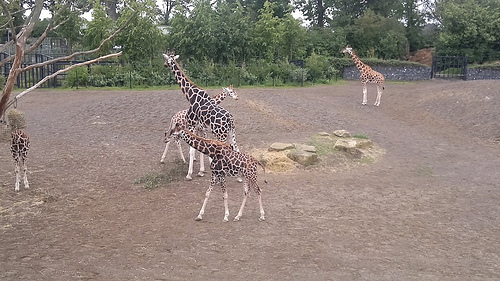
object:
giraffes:
[160, 122, 266, 223]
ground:
[0, 78, 499, 281]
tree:
[0, 0, 132, 125]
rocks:
[286, 150, 320, 163]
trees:
[249, 0, 286, 86]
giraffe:
[337, 46, 386, 107]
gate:
[0, 55, 60, 89]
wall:
[344, 61, 432, 82]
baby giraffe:
[9, 127, 31, 192]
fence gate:
[427, 52, 468, 82]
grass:
[47, 81, 333, 89]